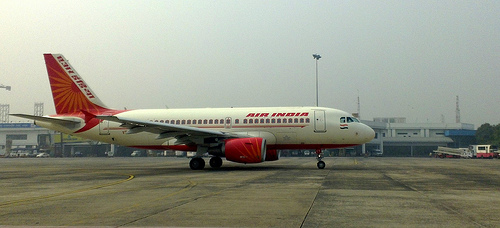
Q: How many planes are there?
A: One.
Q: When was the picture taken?
A: Daytime.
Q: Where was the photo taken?
A: At an airport.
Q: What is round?
A: Wheels.